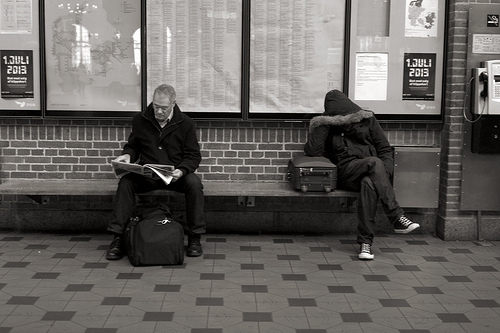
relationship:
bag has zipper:
[121, 206, 185, 269] [160, 217, 168, 226]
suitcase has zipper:
[285, 157, 334, 193] [298, 165, 329, 173]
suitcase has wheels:
[285, 157, 334, 193] [301, 185, 329, 193]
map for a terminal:
[405, 2, 439, 37] [1, 2, 497, 328]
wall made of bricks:
[2, 3, 497, 241] [1, 1, 495, 215]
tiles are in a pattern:
[1, 228, 498, 332] [1, 231, 497, 332]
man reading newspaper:
[108, 83, 204, 259] [110, 160, 173, 184]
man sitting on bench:
[108, 83, 204, 259] [2, 179, 363, 206]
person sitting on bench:
[304, 90, 419, 259] [2, 179, 363, 206]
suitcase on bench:
[285, 157, 334, 193] [2, 179, 363, 206]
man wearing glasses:
[108, 83, 204, 259] [153, 103, 167, 111]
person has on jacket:
[304, 90, 419, 259] [300, 89, 396, 174]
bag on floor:
[121, 206, 185, 269] [0, 233, 497, 332]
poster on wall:
[402, 51, 434, 102] [2, 3, 497, 241]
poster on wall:
[1, 51, 34, 99] [2, 3, 497, 241]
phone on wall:
[463, 59, 499, 122] [2, 3, 497, 241]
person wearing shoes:
[304, 90, 419, 259] [358, 217, 420, 259]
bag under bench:
[121, 206, 185, 269] [2, 179, 363, 206]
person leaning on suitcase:
[304, 90, 419, 259] [285, 157, 334, 193]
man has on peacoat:
[108, 83, 204, 259] [121, 106, 202, 182]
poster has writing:
[402, 51, 434, 102] [407, 54, 434, 77]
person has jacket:
[304, 90, 419, 259] [300, 89, 396, 174]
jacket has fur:
[300, 89, 396, 174] [310, 111, 374, 129]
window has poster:
[2, 1, 344, 111] [402, 51, 434, 102]